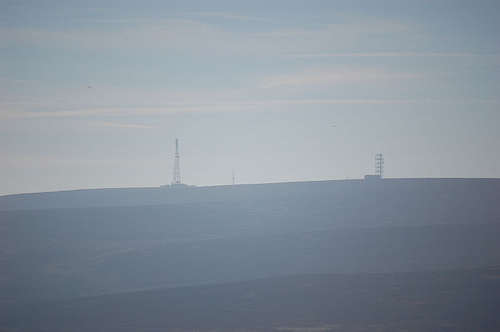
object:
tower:
[171, 136, 182, 186]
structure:
[231, 165, 236, 185]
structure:
[363, 150, 386, 178]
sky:
[1, 2, 499, 196]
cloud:
[2, 97, 500, 115]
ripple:
[1, 190, 499, 214]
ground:
[0, 177, 500, 332]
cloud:
[3, 17, 500, 49]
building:
[364, 173, 380, 181]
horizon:
[0, 177, 500, 200]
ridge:
[4, 266, 499, 311]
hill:
[0, 226, 500, 305]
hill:
[3, 268, 500, 331]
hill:
[0, 195, 500, 244]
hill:
[1, 174, 499, 208]